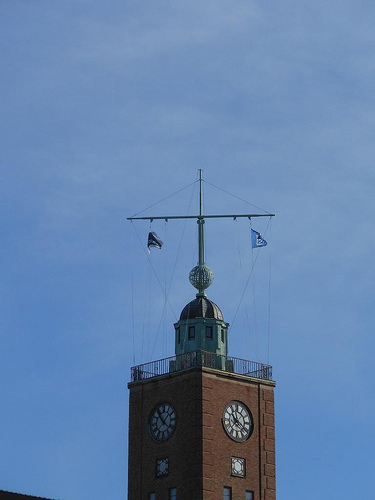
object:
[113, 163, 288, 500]
tower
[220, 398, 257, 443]
clock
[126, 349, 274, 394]
railing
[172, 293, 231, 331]
dome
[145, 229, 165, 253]
flag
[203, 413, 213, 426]
brick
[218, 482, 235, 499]
window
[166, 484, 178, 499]
window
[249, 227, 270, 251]
flags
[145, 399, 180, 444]
clocks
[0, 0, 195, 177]
sky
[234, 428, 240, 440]
numbers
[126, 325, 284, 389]
top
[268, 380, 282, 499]
corner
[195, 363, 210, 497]
corner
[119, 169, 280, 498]
building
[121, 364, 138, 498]
corner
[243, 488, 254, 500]
windows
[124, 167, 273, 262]
mast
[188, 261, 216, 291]
globe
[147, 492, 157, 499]
windows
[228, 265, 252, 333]
cables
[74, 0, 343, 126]
day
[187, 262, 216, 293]
circle